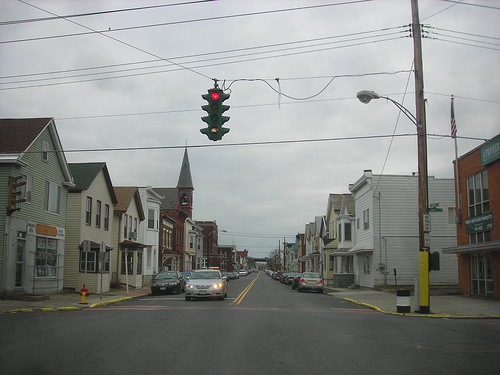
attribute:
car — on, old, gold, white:
[182, 263, 230, 301]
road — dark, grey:
[33, 253, 489, 374]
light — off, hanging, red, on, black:
[192, 79, 248, 147]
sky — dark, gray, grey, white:
[1, 3, 500, 232]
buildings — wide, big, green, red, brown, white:
[2, 114, 250, 297]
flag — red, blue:
[437, 87, 469, 192]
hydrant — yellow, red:
[71, 282, 96, 308]